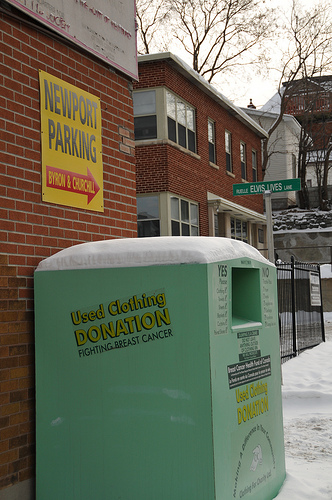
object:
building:
[133, 50, 276, 265]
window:
[186, 106, 197, 153]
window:
[175, 93, 188, 151]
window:
[223, 129, 233, 174]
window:
[206, 116, 218, 169]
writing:
[44, 78, 98, 129]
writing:
[48, 118, 96, 164]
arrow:
[45, 166, 101, 206]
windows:
[133, 87, 158, 141]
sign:
[233, 177, 301, 197]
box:
[34, 235, 286, 498]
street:
[272, 312, 332, 499]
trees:
[177, 5, 275, 90]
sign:
[42, 73, 106, 210]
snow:
[33, 236, 277, 271]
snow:
[278, 347, 326, 485]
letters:
[71, 309, 82, 324]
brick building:
[0, 0, 138, 497]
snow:
[287, 351, 326, 423]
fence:
[277, 261, 326, 365]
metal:
[290, 256, 297, 356]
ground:
[271, 449, 318, 489]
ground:
[289, 361, 325, 481]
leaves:
[298, 28, 325, 58]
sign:
[309, 272, 321, 307]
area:
[298, 351, 327, 497]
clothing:
[249, 443, 263, 471]